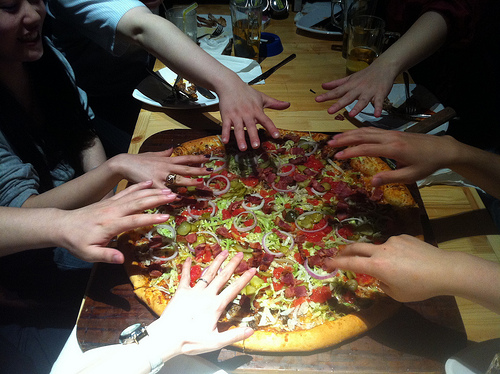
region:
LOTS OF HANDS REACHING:
[59, 62, 468, 364]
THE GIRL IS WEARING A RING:
[153, 167, 180, 198]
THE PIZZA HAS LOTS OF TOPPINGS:
[114, 115, 440, 351]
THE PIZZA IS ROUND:
[112, 120, 432, 367]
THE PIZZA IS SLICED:
[108, 110, 435, 363]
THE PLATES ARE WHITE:
[121, 2, 459, 148]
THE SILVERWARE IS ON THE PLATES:
[121, 50, 460, 140]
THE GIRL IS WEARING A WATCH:
[113, 316, 176, 372]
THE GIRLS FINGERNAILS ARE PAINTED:
[161, 145, 220, 202]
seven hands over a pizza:
[58, 45, 446, 321]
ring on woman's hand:
[108, 137, 220, 224]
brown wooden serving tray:
[380, 322, 482, 372]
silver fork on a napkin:
[196, 21, 227, 45]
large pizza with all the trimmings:
[171, 152, 366, 282]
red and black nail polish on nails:
[186, 146, 219, 196]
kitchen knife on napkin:
[248, 50, 300, 95]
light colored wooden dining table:
[283, 55, 325, 129]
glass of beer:
[336, 15, 405, 82]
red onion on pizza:
[287, 206, 332, 244]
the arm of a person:
[46, 0, 240, 89]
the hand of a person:
[208, 77, 299, 151]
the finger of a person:
[216, 113, 233, 146]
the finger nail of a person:
[218, 132, 230, 145]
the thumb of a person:
[65, 232, 129, 267]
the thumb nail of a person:
[107, 251, 124, 266]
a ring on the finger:
[191, 272, 210, 286]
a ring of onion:
[228, 206, 259, 236]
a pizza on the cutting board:
[111, 125, 427, 359]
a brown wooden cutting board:
[70, 118, 470, 372]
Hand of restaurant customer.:
[168, 250, 261, 355]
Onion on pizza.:
[232, 210, 257, 233]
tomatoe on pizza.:
[310, 285, 332, 303]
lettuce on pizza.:
[255, 213, 274, 235]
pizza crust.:
[259, 318, 376, 350]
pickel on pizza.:
[175, 218, 192, 235]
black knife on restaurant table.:
[248, 51, 302, 85]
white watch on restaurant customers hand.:
[119, 317, 161, 372]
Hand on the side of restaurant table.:
[62, 178, 177, 262]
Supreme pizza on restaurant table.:
[174, 142, 392, 317]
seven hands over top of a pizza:
[37, 34, 464, 363]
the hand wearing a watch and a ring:
[97, 253, 285, 370]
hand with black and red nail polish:
[110, 137, 222, 202]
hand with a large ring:
[102, 141, 222, 202]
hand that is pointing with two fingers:
[311, 222, 477, 330]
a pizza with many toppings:
[112, 108, 433, 353]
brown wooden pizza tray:
[77, 111, 488, 371]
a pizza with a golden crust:
[91, 90, 443, 354]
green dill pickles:
[176, 218, 201, 235]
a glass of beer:
[339, 13, 382, 88]